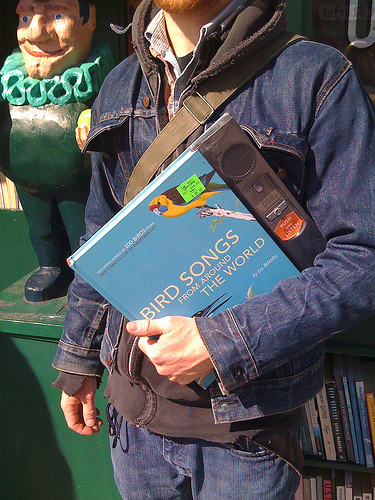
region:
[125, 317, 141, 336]
the thumb nail of a person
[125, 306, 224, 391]
the hand of a person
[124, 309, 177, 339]
the thumb of a person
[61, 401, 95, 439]
the finger of a person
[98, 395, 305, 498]
a pair of blue jeans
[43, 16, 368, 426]
a blue denim jacket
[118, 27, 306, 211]
a brown bag strap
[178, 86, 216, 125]
a buckle on the bag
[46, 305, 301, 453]
a brown shirt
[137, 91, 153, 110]
an orange button on the coat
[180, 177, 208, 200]
the price tag is green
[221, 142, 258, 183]
round speaker on the book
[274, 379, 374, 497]
books on shelves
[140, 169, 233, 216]
bird on cover of book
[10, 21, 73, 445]
statue on a green box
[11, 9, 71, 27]
statue has blue eyes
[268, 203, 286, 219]
button to listen to book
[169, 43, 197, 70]
man is wearing a black tshirt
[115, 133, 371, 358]
man holding a book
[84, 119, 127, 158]
pocket is unbuttoned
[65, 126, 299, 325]
Book of bird songs from around the world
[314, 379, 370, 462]
Books on a shelf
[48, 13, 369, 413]
Blue jean jacket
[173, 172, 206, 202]
Green price tag on a book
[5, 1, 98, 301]
Statue with blue eyes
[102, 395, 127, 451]
String hanging from pocket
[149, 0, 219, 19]
Orange beard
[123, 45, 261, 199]
Strap from a messenger bag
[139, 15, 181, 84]
Open shirt collar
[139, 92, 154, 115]
Metal button on jacket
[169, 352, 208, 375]
veins on person's hand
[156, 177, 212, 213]
green sticker on book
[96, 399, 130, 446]
black string at end of jacket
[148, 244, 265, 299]
pink words on book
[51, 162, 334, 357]
large blue book in hand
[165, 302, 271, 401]
seam on blue jean jacket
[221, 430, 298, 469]
pocket on blue jeans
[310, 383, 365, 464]
lots of books on shelf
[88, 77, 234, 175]
brown strap over man's shoulder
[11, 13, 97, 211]
large statue beside man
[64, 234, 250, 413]
the book is blue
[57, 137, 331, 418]
the book is blue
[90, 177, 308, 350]
the book is blue